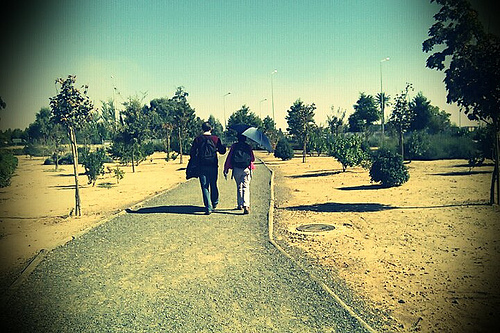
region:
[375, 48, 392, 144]
Light pole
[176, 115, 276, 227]
Two people walking down a gravel path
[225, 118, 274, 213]
Person carrying a black umbrella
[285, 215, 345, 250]
Man hole cover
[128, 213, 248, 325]
Gravel covered path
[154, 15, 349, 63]
Clear blue sky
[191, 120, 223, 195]
Person wearing a black backpack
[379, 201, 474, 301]
Sand covered ground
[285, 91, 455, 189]
Row of various kinds of trees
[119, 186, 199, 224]
Shadow from couple walking down gravel path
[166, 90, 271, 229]
a couple walking down a path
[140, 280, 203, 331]
gravel scattered over the path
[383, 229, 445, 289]
brown dirt on the side of the path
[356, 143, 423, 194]
a dark green shrub growing in the sand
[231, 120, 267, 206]
a woman carrying a black umbrella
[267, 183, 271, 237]
wooden edge marking the path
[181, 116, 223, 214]
a man carrying a black backpack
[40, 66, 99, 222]
a thin fruit tree growing near the path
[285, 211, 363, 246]
a man hole cover encased in cement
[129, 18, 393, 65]
a bright blue sky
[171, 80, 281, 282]
Two people walking down the walkway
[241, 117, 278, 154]
A black umbrella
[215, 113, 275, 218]
A person holding an umbrella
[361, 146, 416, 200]
A small bush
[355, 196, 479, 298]
Sand on the side of the sidewalk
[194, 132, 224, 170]
A black book bag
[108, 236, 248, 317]
A paved walkway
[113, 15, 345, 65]
A clear, blue sky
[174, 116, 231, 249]
A man walking down the walkway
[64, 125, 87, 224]
A skinny tree trunk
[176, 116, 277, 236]
Two people walking on a path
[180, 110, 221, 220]
A person walking on a path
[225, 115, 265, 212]
A person with an umbrella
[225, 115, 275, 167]
A blue umbrella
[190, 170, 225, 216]
The legs of a person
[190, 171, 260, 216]
The legs of two people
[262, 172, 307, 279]
The edge of a path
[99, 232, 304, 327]
A gravel walking path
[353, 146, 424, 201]
A green bush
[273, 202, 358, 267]
A man hole cover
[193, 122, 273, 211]
this is a man and a woman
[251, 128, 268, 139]
the woman is carrying an aumbrella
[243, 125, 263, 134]
the umbrella is black in color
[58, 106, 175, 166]
these are trees beside the road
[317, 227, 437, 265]
the soil is brown in color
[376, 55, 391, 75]
this is a street light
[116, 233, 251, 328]
the road is tarmacked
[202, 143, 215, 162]
the man is carrying a bag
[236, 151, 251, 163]
the bag is black in color